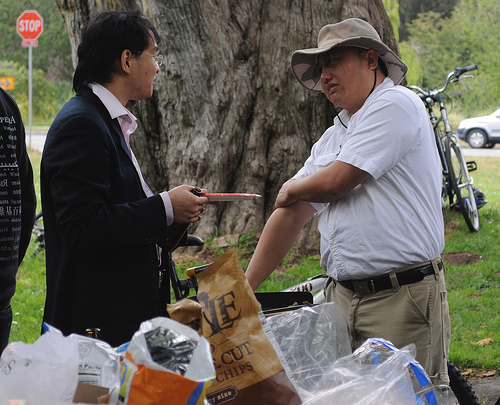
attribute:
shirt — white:
[289, 75, 470, 290]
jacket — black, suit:
[31, 78, 180, 343]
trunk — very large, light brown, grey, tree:
[51, 0, 410, 288]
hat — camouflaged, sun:
[282, 11, 428, 109]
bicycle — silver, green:
[398, 53, 496, 239]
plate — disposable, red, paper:
[194, 181, 263, 214]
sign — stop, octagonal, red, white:
[5, 5, 49, 50]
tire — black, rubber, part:
[438, 353, 479, 403]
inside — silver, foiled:
[140, 323, 198, 379]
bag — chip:
[96, 296, 221, 402]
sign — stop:
[9, 5, 49, 53]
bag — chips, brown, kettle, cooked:
[173, 242, 310, 402]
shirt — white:
[290, 71, 450, 292]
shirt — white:
[301, 100, 444, 308]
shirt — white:
[306, 90, 425, 280]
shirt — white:
[294, 101, 433, 282]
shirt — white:
[295, 109, 444, 268]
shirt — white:
[292, 77, 459, 295]